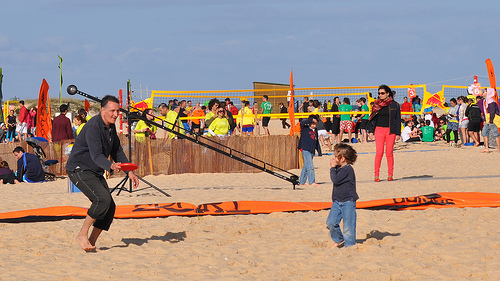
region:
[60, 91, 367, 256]
a man and a child playing Frisbee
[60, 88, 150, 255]
man holds a Frisbee in right hand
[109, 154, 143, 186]
Frisbee is red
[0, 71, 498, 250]
many people in the beach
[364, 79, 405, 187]
woman wears red pants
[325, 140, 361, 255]
kid wears blue jeans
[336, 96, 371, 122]
two man wearing green shorts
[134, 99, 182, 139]
a couple wearing yellow shorts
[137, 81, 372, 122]
orange and yellow nets in middle of people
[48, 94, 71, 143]
man wears a red top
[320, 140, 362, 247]
A kid in blue jeans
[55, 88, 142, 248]
A man with a frisbee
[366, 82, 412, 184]
A woman in pink pants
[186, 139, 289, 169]
A wooden fence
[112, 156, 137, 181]
A red frisbee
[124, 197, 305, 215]
An orange banner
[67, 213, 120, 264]
A mans barefeet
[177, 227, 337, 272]
Yellow sand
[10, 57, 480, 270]
A beach with people playing on it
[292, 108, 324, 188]
A lady wearing jeans and walking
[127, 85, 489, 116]
A yellow volleyball net.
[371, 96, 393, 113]
A red scarf.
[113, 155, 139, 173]
A red frisbee.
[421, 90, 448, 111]
A red bull logo.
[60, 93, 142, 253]
A man throwing a frisbee.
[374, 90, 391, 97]
A pair of sunglasses.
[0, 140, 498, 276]
Beige colored sand.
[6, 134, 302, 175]
A small wooden fence.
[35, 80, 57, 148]
An orange long flag.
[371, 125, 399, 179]
A pair of peach colored skinny legged jeans.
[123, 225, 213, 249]
shadow in the sand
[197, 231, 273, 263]
red sand on the ground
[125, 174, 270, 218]
orange banner on the sand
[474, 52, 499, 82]
orange sign blowing in the wind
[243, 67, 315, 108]
tall brown sand with black roof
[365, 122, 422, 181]
woman wearing pink pants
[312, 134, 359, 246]
boy standing in sand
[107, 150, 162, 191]
man throwing pink frisbee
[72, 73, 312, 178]
black equipment in the sand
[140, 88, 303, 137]
people standing in the sand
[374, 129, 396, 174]
The woman's pants are red.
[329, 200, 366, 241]
The child is wearing jeans.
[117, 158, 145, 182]
The Frisbee is red.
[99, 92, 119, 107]
The man has black hair.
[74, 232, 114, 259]
The man has no shoes on.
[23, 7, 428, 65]
The sky is clear.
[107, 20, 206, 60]
The sky is blue.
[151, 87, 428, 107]
The volleyball net is yellow.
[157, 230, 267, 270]
The ground is sand.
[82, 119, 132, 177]
The man is wearing a black shirt.